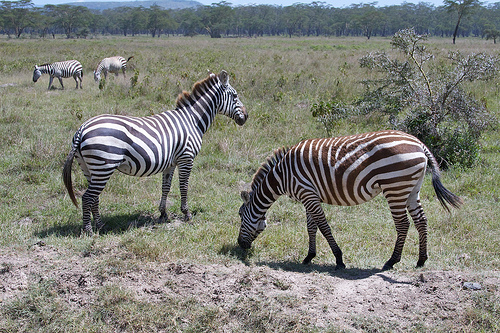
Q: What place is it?
A: It is a field.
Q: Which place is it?
A: It is a field.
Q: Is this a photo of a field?
A: Yes, it is showing a field.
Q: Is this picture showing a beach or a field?
A: It is showing a field.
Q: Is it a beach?
A: No, it is a field.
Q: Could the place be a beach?
A: No, it is a field.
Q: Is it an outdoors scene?
A: Yes, it is outdoors.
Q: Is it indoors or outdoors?
A: It is outdoors.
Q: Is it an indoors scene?
A: No, it is outdoors.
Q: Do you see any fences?
A: No, there are no fences.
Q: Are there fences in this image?
A: No, there are no fences.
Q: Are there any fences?
A: No, there are no fences.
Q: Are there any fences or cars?
A: No, there are no fences or cars.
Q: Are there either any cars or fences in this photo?
A: No, there are no fences or cars.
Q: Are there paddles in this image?
A: No, there are no paddles.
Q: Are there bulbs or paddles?
A: No, there are no paddles or bulbs.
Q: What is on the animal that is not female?
A: The dirt is on the zebra.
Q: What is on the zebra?
A: The dirt is on the zebra.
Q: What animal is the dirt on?
A: The dirt is on the zebra.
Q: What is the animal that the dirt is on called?
A: The animal is a zebra.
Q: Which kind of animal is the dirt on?
A: The dirt is on the zebra.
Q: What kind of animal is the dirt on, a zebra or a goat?
A: The dirt is on a zebra.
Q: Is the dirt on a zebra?
A: Yes, the dirt is on a zebra.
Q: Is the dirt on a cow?
A: No, the dirt is on a zebra.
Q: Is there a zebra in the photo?
A: Yes, there is a zebra.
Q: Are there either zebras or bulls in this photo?
A: Yes, there is a zebra.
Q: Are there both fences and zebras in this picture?
A: No, there is a zebra but no fences.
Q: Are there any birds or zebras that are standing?
A: Yes, the zebra is standing.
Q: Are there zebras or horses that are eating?
A: Yes, the zebra is eating.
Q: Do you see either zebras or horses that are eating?
A: Yes, the zebra is eating.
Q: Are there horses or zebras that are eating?
A: Yes, the zebra is eating.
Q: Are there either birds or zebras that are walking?
A: Yes, the zebra is walking.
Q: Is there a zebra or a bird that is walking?
A: Yes, the zebra is walking.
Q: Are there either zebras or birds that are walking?
A: Yes, the zebra is walking.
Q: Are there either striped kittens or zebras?
A: Yes, there is a striped zebra.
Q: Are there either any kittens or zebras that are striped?
A: Yes, the zebra is striped.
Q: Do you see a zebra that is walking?
A: Yes, there is a zebra that is walking.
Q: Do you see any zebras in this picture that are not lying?
A: Yes, there is a zebra that is walking .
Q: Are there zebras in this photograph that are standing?
A: Yes, there is a zebra that is standing.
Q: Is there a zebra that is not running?
A: Yes, there is a zebra that is standing.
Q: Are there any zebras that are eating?
A: Yes, there is a zebra that is eating.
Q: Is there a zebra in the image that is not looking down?
A: Yes, there is a zebra that is eating.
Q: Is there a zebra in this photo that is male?
A: Yes, there is a male zebra.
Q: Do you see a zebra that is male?
A: Yes, there is a zebra that is male.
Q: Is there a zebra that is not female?
A: Yes, there is a male zebra.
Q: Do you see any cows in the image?
A: No, there are no cows.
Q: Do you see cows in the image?
A: No, there are no cows.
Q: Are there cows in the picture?
A: No, there are no cows.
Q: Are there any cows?
A: No, there are no cows.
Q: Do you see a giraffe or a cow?
A: No, there are no cows or giraffes.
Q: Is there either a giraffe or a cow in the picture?
A: No, there are no cows or giraffes.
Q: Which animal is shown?
A: The animal is a zebra.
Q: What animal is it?
A: The animal is a zebra.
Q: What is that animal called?
A: This is a zebra.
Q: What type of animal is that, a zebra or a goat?
A: This is a zebra.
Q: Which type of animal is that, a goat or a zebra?
A: This is a zebra.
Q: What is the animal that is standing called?
A: The animal is a zebra.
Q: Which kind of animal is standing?
A: The animal is a zebra.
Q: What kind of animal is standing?
A: The animal is a zebra.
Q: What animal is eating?
A: The animal is a zebra.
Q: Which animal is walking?
A: The animal is a zebra.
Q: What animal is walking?
A: The animal is a zebra.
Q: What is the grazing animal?
A: The animal is a zebra.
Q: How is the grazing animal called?
A: The animal is a zebra.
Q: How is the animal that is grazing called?
A: The animal is a zebra.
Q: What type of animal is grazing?
A: The animal is a zebra.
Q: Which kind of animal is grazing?
A: The animal is a zebra.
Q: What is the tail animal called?
A: The animal is a zebra.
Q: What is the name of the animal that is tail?
A: The animal is a zebra.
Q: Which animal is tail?
A: The animal is a zebra.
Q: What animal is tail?
A: The animal is a zebra.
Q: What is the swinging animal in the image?
A: The animal is a zebra.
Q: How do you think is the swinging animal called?
A: The animal is a zebra.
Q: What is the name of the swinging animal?
A: The animal is a zebra.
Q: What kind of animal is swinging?
A: The animal is a zebra.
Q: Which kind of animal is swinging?
A: The animal is a zebra.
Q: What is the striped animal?
A: The animal is a zebra.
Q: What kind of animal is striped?
A: The animal is a zebra.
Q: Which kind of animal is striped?
A: The animal is a zebra.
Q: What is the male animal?
A: The animal is a zebra.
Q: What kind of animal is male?
A: The animal is a zebra.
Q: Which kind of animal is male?
A: The animal is a zebra.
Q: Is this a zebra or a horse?
A: This is a zebra.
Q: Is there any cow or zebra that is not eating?
A: No, there is a zebra but he is eating.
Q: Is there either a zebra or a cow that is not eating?
A: No, there is a zebra but he is eating.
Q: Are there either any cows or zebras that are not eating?
A: No, there is a zebra but he is eating.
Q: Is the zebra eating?
A: Yes, the zebra is eating.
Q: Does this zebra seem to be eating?
A: Yes, the zebra is eating.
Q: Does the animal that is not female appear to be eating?
A: Yes, the zebra is eating.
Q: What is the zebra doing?
A: The zebra is eating.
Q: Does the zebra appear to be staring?
A: No, the zebra is eating.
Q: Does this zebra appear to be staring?
A: No, the zebra is eating.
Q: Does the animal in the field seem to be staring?
A: No, the zebra is eating.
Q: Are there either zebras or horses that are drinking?
A: No, there is a zebra but he is eating.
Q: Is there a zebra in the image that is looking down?
A: No, there is a zebra but he is eating.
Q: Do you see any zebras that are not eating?
A: No, there is a zebra but he is eating.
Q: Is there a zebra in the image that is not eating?
A: No, there is a zebra but he is eating.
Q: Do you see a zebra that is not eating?
A: No, there is a zebra but he is eating.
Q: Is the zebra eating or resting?
A: The zebra is eating.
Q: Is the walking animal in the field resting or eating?
A: The zebra is eating.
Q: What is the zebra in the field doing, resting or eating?
A: The zebra is eating.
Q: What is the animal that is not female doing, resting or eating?
A: The zebra is eating.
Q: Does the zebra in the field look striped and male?
A: Yes, the zebra is striped and male.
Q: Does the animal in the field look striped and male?
A: Yes, the zebra is striped and male.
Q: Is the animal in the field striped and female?
A: No, the zebra is striped but male.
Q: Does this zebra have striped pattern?
A: Yes, the zebra is striped.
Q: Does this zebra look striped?
A: Yes, the zebra is striped.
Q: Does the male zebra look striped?
A: Yes, the zebra is striped.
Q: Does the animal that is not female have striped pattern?
A: Yes, the zebra is striped.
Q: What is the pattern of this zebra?
A: The zebra is striped.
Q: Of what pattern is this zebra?
A: The zebra is striped.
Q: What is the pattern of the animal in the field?
A: The zebra is striped.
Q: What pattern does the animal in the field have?
A: The zebra has striped pattern.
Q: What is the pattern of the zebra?
A: The zebra is striped.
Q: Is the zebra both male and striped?
A: Yes, the zebra is male and striped.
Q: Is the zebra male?
A: Yes, the zebra is male.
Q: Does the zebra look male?
A: Yes, the zebra is male.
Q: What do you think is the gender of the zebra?
A: The zebra is male.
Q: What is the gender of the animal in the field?
A: The zebra is male.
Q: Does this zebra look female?
A: No, the zebra is male.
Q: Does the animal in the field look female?
A: No, the zebra is male.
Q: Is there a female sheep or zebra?
A: No, there is a zebra but he is male.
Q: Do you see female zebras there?
A: No, there is a zebra but he is male.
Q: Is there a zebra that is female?
A: No, there is a zebra but he is male.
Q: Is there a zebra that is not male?
A: No, there is a zebra but he is male.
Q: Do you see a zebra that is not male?
A: No, there is a zebra but he is male.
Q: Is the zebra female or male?
A: The zebra is male.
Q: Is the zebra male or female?
A: The zebra is male.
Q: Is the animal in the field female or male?
A: The zebra is male.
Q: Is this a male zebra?
A: Yes, this is a male zebra.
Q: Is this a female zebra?
A: No, this is a male zebra.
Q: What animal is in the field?
A: The zebra is in the field.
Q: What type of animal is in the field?
A: The animal is a zebra.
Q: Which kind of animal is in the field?
A: The animal is a zebra.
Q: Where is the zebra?
A: The zebra is in the field.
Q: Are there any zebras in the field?
A: Yes, there is a zebra in the field.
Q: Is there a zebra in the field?
A: Yes, there is a zebra in the field.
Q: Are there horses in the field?
A: No, there is a zebra in the field.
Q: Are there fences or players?
A: No, there are no fences or players.